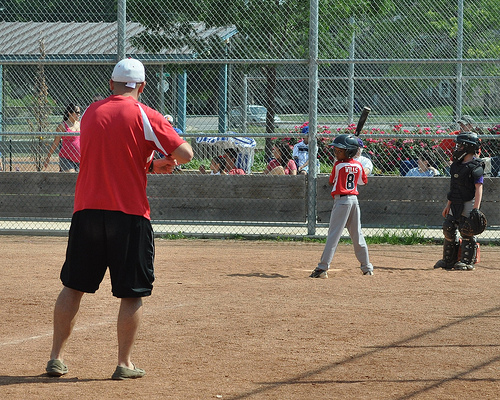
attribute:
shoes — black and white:
[29, 343, 161, 385]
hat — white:
[107, 55, 148, 85]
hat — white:
[105, 54, 147, 89]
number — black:
[345, 173, 352, 190]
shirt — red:
[403, 167, 442, 176]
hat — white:
[108, 58, 143, 98]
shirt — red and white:
[77, 89, 178, 222]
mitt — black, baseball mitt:
[464, 207, 484, 233]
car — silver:
[221, 90, 290, 139]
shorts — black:
[58, 210, 154, 297]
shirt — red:
[63, 100, 73, 158]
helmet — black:
[324, 125, 364, 241]